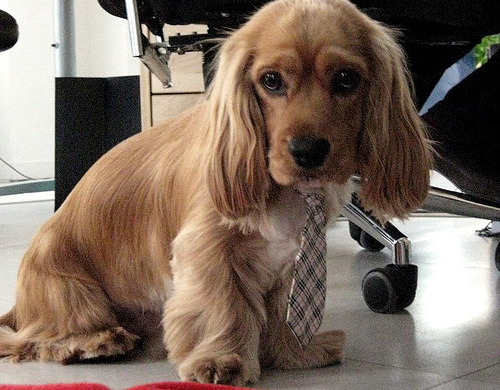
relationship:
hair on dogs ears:
[211, 53, 265, 216] [158, 5, 427, 232]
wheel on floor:
[361, 265, 418, 312] [0, 189, 498, 387]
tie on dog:
[281, 182, 329, 351] [0, 1, 439, 388]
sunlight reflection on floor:
[402, 212, 497, 337] [0, 189, 498, 387]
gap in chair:
[424, 29, 498, 110] [99, 1, 499, 309]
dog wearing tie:
[0, 1, 439, 388] [284, 184, 331, 351]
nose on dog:
[287, 135, 335, 169] [0, 1, 439, 388]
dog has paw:
[0, 1, 439, 388] [162, 354, 272, 388]